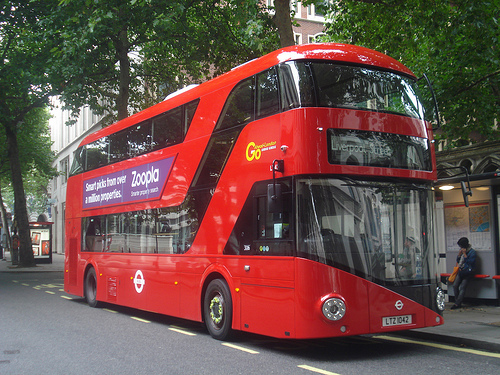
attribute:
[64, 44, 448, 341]
bus — red, double decker, parked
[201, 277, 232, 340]
tire — red, black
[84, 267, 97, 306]
tire — back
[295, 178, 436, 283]
windshield — driver's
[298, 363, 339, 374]
line — white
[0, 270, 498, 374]
street — grey, concrete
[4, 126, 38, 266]
trunk — tree trunk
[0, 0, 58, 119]
leaves — green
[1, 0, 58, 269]
tree — tall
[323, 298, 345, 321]
headlight — round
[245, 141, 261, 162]
go — yellow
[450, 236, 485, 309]
person — sitting, sitting down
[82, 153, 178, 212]
sign — purple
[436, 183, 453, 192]
light — on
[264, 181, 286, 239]
mirror — side view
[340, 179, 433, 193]
wiper — bus's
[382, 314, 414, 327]
plate — bus's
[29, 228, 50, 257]
banner — displayed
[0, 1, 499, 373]
photo — outdoors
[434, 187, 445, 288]
mirror — driver's